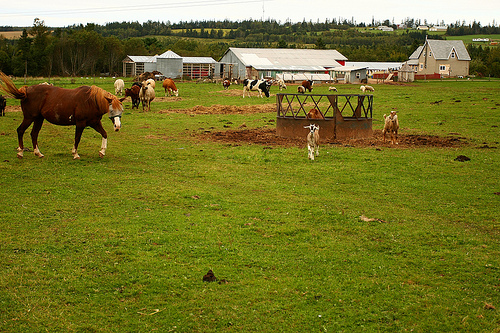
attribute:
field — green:
[100, 197, 360, 287]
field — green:
[3, 80, 495, 328]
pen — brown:
[268, 87, 378, 140]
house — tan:
[396, 40, 471, 77]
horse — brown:
[0, 68, 127, 163]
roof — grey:
[426, 37, 471, 61]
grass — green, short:
[240, 174, 466, 311]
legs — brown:
[70, 109, 113, 161]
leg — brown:
[88, 120, 109, 159]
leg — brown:
[67, 124, 86, 161]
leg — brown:
[29, 119, 45, 159]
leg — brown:
[13, 113, 33, 158]